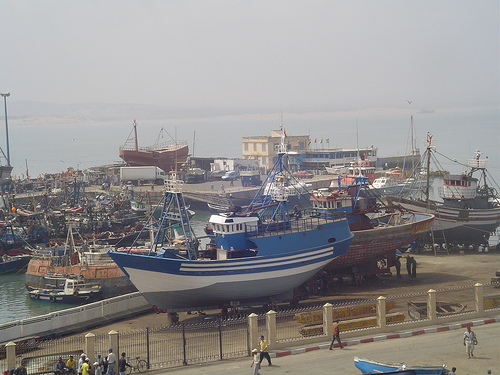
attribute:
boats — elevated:
[107, 207, 353, 320]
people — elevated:
[393, 251, 403, 280]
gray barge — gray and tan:
[8, 267, 118, 312]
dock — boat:
[2, 151, 498, 373]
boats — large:
[105, 171, 349, 303]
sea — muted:
[15, 117, 497, 179]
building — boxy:
[241, 127, 313, 175]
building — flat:
[208, 155, 266, 176]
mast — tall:
[0, 91, 12, 178]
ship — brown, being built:
[119, 118, 193, 173]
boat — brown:
[340, 209, 447, 270]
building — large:
[227, 133, 332, 193]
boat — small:
[29, 279, 101, 300]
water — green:
[0, 252, 100, 328]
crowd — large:
[32, 332, 112, 372]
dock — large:
[146, 221, 404, 327]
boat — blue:
[101, 195, 304, 278]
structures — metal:
[199, 153, 330, 241]